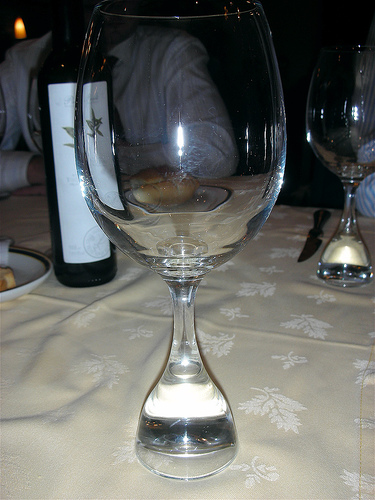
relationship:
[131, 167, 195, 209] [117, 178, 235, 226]
roll on plate